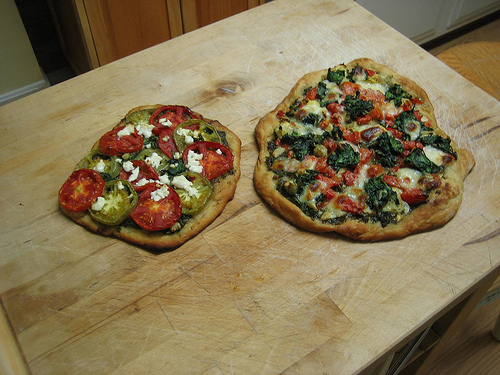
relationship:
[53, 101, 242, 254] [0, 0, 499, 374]
pizza on table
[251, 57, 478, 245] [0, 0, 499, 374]
pizza on table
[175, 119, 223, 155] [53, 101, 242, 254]
tomato on pizza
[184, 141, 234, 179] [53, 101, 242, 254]
tomato on pizza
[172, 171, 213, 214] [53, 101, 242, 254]
tomato on pizza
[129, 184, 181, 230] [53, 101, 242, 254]
tomato on pizza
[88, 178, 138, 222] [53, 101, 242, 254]
tomato on pizza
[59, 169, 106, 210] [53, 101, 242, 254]
tomato on pizza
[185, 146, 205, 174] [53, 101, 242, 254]
feta cheese on pizza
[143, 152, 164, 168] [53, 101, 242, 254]
feta cheese on pizza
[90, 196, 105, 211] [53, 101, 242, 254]
feta cheese on pizza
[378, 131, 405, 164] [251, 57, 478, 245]
spinach on pizza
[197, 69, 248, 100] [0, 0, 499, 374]
spot on table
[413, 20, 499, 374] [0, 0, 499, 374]
floor underneath table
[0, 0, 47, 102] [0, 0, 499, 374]
wall behind table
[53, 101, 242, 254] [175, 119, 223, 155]
pizza contains tomato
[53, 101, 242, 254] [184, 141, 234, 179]
pizza contains tomato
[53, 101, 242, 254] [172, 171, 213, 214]
pizza contains tomato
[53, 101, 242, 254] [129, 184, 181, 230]
pizza contains tomato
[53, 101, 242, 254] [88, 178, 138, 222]
pizza contains tomato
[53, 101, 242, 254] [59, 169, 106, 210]
pizza contains tomato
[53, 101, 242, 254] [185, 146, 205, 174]
pizza contains feta cheese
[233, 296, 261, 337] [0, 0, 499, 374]
line on table